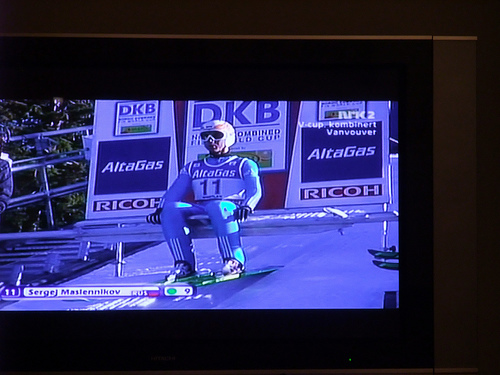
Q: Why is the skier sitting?
A: He is preparing to jump.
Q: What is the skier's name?
A: Sergej Masiennikov.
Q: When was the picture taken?
A: During the day.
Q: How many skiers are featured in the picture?
A: One.